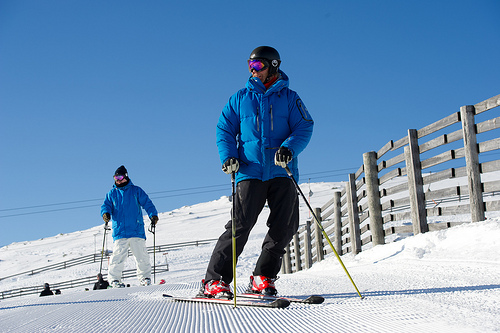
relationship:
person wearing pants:
[94, 162, 161, 290] [105, 233, 159, 287]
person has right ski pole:
[200, 44, 347, 324] [281, 159, 370, 299]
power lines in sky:
[8, 158, 380, 221] [3, 1, 499, 241]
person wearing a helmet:
[200, 44, 347, 324] [253, 46, 286, 76]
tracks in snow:
[44, 277, 466, 332] [13, 177, 498, 332]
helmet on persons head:
[253, 46, 286, 76] [239, 43, 294, 92]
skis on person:
[150, 277, 340, 316] [200, 44, 347, 324]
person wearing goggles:
[200, 44, 347, 324] [247, 60, 270, 74]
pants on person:
[204, 165, 308, 282] [200, 44, 347, 324]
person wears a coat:
[200, 44, 347, 324] [215, 67, 314, 184]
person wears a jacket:
[94, 162, 161, 290] [100, 180, 164, 238]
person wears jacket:
[94, 162, 161, 290] [100, 180, 164, 238]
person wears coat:
[200, 44, 347, 324] [215, 67, 314, 184]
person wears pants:
[94, 162, 161, 290] [105, 233, 159, 287]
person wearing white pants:
[94, 162, 161, 290] [105, 233, 159, 287]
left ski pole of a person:
[88, 206, 117, 289] [94, 162, 161, 290]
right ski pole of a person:
[141, 221, 176, 287] [94, 162, 161, 290]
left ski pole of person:
[222, 156, 250, 319] [200, 44, 347, 324]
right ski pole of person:
[282, 159, 375, 306] [200, 44, 347, 324]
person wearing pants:
[200, 44, 347, 324] [204, 165, 308, 282]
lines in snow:
[143, 299, 255, 332] [13, 177, 498, 332]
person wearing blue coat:
[200, 44, 347, 324] [215, 67, 314, 184]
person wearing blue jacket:
[94, 162, 161, 290] [100, 180, 164, 238]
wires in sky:
[8, 158, 380, 221] [3, 1, 499, 241]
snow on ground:
[13, 177, 498, 332] [25, 221, 499, 317]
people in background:
[28, 274, 127, 298] [6, 101, 316, 294]